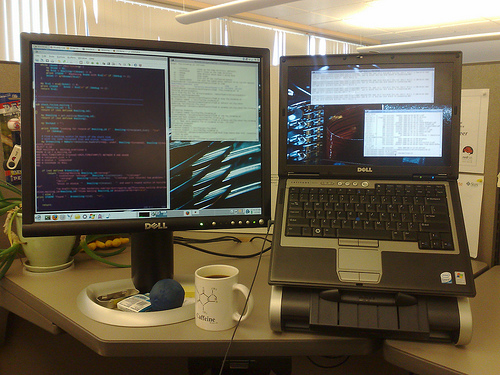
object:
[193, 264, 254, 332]
coffee cup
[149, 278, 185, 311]
ball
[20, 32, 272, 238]
monitor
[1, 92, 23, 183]
pez dispenser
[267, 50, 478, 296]
laptop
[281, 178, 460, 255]
keyboard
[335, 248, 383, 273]
touch pad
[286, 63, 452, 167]
screen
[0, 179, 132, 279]
plant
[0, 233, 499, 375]
desk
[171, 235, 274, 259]
wires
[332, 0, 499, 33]
flourescent light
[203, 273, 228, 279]
coffee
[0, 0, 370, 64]
blinds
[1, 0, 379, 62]
window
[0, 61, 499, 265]
wall